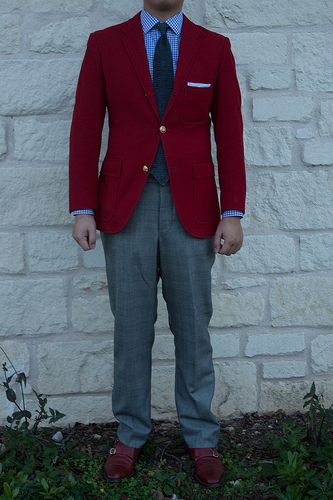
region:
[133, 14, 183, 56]
blue and white shirt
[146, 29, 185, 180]
man has blue tie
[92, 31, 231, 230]
man has red coat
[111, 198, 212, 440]
man has grey slacks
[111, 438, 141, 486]
man has brown shoes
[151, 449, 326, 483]
green plants on ground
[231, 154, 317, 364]
grey and stone wall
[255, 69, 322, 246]
stone wall behind man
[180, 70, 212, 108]
white card in pocket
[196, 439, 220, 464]
silver buckle on shoes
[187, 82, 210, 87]
A white hanky issticking out of a pocket.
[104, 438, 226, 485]
Two shoes are brown.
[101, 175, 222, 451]
The pants are gray.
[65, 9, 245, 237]
A jacket is red.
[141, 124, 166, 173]
Two buttons are gold.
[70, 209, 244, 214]
The cuffs are blue and white.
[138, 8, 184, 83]
A shirt is blue and white.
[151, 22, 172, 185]
The tie is gray.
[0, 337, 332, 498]
Some green leaves are on the ground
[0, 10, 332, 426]
A wall is white stone.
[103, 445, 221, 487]
red dress shoes with strap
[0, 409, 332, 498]
green weeds in rocky soil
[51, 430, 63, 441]
grey rock sitting on ground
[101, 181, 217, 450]
grey dress pants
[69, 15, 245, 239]
red blazer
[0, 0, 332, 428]
white rock wall behind person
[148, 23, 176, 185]
a grey tie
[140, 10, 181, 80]
blue and white collared dress shirt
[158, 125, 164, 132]
gold button on red blazer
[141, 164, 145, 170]
gold button on red blazer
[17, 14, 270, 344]
this is a man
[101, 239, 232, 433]
the man is wearing gray pants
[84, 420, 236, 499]
these are brown shoes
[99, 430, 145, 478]
the shoes are made of leather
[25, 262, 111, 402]
the wall is stone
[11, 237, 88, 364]
the stone wall is white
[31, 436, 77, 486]
the ground here is leaves and dirt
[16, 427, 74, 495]
the leaves are dark green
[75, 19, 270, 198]
the man has a red jacket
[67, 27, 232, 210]
the man is wearing a suit